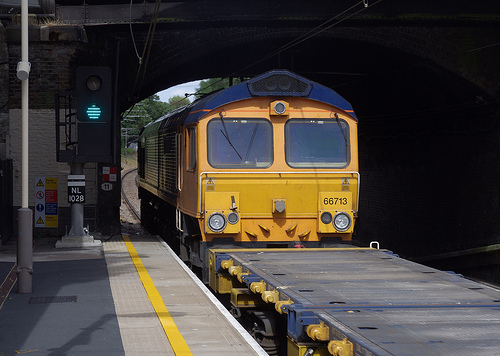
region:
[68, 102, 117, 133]
the light is green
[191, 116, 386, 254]
the two windows are square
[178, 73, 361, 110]
the top of the train is blue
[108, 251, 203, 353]
the line is yellow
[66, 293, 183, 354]
there is shadow on the floor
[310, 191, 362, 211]
the numbers are 66713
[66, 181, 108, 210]
the white letters are nl8028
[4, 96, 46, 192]
the post is white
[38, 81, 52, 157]
the wall is made of bricks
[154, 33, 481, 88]
the wall is dome shaped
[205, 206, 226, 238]
headlight on a train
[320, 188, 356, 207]
numbers on a train engine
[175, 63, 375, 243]
front of a train engine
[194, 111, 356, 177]
front windows on a train engin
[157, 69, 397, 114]
roof of a train engine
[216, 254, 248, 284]
yellow lights on a train car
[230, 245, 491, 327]
flat bed of a train car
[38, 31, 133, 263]
light signal that is green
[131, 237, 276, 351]
a train station platform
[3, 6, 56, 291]
pole on a train station platform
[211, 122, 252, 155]
part of a window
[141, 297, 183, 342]
part of a yellow strip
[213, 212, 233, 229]
part of a headlight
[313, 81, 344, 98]
edge of the train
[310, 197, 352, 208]
part of a number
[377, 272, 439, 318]
part of a surface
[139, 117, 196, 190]
side of a train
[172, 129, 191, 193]
part of a metal handle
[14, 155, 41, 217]
part of a post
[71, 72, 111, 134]
part of a traffic light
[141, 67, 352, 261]
Yellow and blue train car.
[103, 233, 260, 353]
Train platform with yellow caution line.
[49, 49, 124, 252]
Traffic signal on train platform.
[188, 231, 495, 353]
Train car with flat pallet.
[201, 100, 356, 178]
Large rectangular windows on locomotive engine.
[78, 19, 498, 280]
Train emerging from a tunnel.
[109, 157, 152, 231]
Curved train tracks.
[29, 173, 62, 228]
Warning sign on a wall.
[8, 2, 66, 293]
Tall metal pole with concrete base.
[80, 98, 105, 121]
Green light emanating from black box.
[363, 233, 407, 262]
large silver bolt on tracks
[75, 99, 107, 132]
circular blue light in the background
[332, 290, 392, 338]
holes on the equipment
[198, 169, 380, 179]
large thin silver railing on train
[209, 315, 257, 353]
white edge of track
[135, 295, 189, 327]
yello wide yellow line on platform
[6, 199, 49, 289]
gray base of large pole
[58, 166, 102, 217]
white and black lines on platform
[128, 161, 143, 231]
black curved train tracks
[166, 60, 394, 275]
large yellow train with blue roof